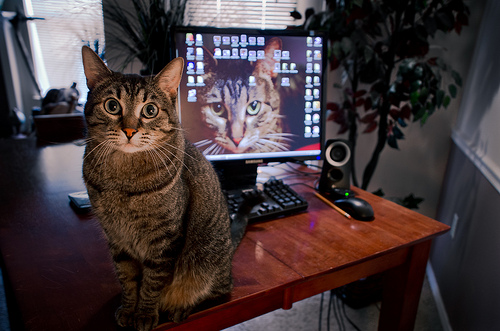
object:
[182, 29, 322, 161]
monitor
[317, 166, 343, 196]
webcam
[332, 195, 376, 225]
mouse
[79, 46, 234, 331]
cat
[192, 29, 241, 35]
black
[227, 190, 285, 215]
black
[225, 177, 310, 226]
keyboard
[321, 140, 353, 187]
black and silver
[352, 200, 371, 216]
black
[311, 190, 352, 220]
pencil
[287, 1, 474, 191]
indoor tree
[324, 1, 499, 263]
corner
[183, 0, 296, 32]
window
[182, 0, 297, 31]
mini blinds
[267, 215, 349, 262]
brown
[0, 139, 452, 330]
table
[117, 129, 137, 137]
orange nose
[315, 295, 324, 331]
black wires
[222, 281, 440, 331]
floor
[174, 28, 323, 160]
wallpaper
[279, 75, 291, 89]
icons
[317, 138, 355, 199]
speaker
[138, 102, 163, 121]
eyes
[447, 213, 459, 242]
electrical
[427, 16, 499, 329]
wall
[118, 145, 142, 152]
white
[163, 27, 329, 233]
computer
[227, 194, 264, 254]
tail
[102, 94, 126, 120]
cat's eyes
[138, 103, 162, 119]
round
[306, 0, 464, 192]
plant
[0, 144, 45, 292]
shadow